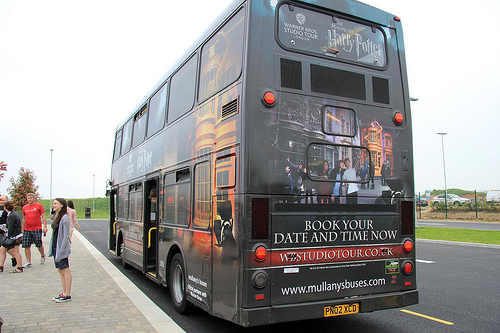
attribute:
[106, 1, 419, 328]
bus — black, tall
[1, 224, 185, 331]
sidewalk — brick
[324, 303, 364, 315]
license plate — yellow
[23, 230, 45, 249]
shorts — plaid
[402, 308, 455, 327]
line — yellow